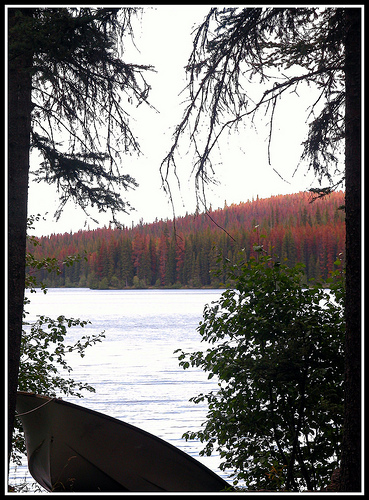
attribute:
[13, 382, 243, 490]
boat — pulled up, sticking up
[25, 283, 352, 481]
lake — calm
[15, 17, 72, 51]
leaves — green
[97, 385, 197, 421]
water — clear, blue, white, lake, riply, choppy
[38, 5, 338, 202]
sky — blue, gray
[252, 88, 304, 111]
twigs — hanging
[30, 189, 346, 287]
hill — covered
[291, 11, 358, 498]
tree — evergreen, tall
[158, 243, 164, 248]
leaves — red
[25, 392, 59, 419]
rope — attached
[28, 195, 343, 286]
forest — colorful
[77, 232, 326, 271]
trees — green, changing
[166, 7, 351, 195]
branches — dangling